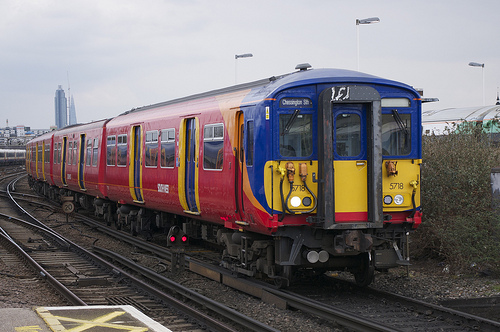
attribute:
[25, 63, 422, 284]
train — colorful, yellow, red, blue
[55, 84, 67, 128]
building — tall, high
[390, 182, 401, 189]
numbers — black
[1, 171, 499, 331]
train tracks — rusty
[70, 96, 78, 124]
building — tall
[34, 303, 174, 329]
platform — painted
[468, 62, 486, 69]
flag — flying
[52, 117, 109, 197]
train car — colorful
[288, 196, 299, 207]
light — yellow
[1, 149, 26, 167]
train — white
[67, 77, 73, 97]
lightpole — tall